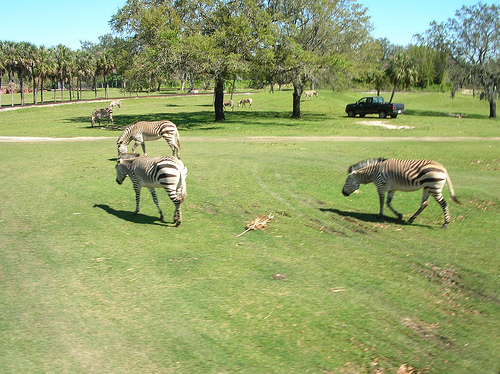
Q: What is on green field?
A: Zebras.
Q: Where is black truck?
A: In background.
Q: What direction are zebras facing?
A: The left.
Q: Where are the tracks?
A: On green grass.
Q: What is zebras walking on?
A: The grass.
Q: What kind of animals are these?
A: Zebras.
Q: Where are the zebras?
A: Field.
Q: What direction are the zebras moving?
A: Left.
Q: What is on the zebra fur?
A: Stripes.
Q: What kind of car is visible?
A: Black truck.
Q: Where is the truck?
A: Parked next to a tree.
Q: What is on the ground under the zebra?
A: Shadow.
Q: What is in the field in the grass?
A: Trees.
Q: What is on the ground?
A: Grass.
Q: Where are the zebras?
A: A field.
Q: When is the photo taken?
A: Sunny day.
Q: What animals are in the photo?
A: Zebras.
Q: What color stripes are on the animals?
A: Black.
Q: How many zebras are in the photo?
A: 7.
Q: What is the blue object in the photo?
A: A truck.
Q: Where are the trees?
A: Center of the field.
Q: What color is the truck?
A: Blue.